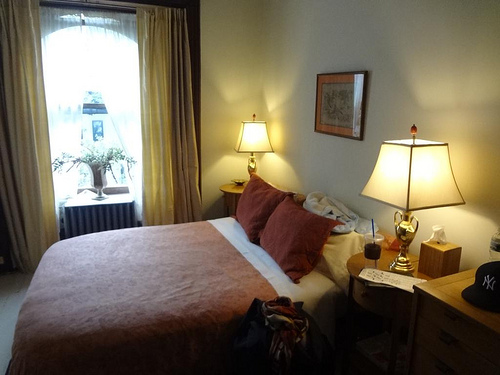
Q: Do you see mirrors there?
A: No, there are no mirrors.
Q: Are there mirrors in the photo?
A: No, there are no mirrors.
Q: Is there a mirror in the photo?
A: No, there are no mirrors.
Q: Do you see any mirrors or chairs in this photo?
A: No, there are no mirrors or chairs.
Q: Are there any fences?
A: No, there are no fences.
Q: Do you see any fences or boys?
A: No, there are no fences or boys.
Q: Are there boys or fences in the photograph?
A: No, there are no fences or boys.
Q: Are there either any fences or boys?
A: No, there are no fences or boys.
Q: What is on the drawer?
A: The cap is on the drawer.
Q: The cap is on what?
A: The cap is on the drawer.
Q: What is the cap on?
A: The cap is on the drawer.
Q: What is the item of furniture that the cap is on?
A: The piece of furniture is a drawer.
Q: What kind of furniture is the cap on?
A: The cap is on the drawer.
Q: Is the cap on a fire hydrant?
A: No, the cap is on a drawer.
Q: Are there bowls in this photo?
A: No, there are no bowls.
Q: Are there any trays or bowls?
A: No, there are no bowls or trays.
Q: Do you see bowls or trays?
A: No, there are no bowls or trays.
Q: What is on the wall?
A: The painting is on the wall.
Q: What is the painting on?
A: The painting is on the wall.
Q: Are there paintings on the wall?
A: Yes, there is a painting on the wall.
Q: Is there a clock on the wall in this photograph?
A: No, there is a painting on the wall.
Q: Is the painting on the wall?
A: Yes, the painting is on the wall.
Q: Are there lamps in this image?
A: Yes, there is a lamp.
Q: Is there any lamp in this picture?
A: Yes, there is a lamp.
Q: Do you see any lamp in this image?
A: Yes, there is a lamp.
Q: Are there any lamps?
A: Yes, there is a lamp.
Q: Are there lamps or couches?
A: Yes, there is a lamp.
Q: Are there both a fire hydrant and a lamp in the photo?
A: No, there is a lamp but no fire hydrants.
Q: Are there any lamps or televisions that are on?
A: Yes, the lamp is on.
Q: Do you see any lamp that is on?
A: Yes, there is a lamp that is on.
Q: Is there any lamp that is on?
A: Yes, there is a lamp that is on.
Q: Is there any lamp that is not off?
A: Yes, there is a lamp that is on.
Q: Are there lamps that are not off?
A: Yes, there is a lamp that is on.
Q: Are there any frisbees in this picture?
A: No, there are no frisbees.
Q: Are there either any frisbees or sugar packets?
A: No, there are no frisbees or sugar packets.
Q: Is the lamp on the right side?
A: Yes, the lamp is on the right of the image.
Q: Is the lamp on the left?
A: No, the lamp is on the right of the image.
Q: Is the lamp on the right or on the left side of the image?
A: The lamp is on the right of the image.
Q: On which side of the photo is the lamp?
A: The lamp is on the right of the image.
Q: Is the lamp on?
A: Yes, the lamp is on.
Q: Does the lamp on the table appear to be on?
A: Yes, the lamp is on.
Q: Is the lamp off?
A: No, the lamp is on.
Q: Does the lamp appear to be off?
A: No, the lamp is on.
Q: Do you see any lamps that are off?
A: No, there is a lamp but it is on.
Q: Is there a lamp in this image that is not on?
A: No, there is a lamp but it is on.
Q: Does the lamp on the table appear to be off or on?
A: The lamp is on.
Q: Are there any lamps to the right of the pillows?
A: Yes, there is a lamp to the right of the pillows.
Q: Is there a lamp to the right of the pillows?
A: Yes, there is a lamp to the right of the pillows.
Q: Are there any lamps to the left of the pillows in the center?
A: No, the lamp is to the right of the pillows.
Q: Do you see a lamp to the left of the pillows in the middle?
A: No, the lamp is to the right of the pillows.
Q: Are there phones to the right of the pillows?
A: No, there is a lamp to the right of the pillows.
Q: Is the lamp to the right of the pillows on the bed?
A: Yes, the lamp is to the right of the pillows.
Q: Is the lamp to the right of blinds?
A: No, the lamp is to the right of the pillows.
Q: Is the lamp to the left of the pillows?
A: No, the lamp is to the right of the pillows.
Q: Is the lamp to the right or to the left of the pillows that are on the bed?
A: The lamp is to the right of the pillows.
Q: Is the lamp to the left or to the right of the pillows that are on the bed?
A: The lamp is to the right of the pillows.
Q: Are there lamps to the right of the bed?
A: Yes, there is a lamp to the right of the bed.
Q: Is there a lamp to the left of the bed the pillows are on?
A: No, the lamp is to the right of the bed.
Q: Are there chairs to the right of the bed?
A: No, there is a lamp to the right of the bed.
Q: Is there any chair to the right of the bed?
A: No, there is a lamp to the right of the bed.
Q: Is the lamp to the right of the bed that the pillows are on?
A: Yes, the lamp is to the right of the bed.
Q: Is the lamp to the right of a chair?
A: No, the lamp is to the right of the bed.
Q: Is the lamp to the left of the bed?
A: No, the lamp is to the right of the bed.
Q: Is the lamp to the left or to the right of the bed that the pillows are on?
A: The lamp is to the right of the bed.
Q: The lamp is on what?
A: The lamp is on the table.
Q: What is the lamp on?
A: The lamp is on the table.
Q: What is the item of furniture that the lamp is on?
A: The piece of furniture is a table.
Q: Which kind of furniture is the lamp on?
A: The lamp is on the table.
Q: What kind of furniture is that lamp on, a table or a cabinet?
A: The lamp is on a table.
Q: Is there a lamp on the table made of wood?
A: Yes, there is a lamp on the table.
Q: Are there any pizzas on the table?
A: No, there is a lamp on the table.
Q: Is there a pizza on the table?
A: No, there is a lamp on the table.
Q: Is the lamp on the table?
A: Yes, the lamp is on the table.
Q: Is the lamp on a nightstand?
A: No, the lamp is on the table.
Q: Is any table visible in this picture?
A: Yes, there is a table.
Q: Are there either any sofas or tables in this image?
A: Yes, there is a table.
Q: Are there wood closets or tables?
A: Yes, there is a wood table.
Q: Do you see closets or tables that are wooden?
A: Yes, the table is wooden.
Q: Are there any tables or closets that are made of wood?
A: Yes, the table is made of wood.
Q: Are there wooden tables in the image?
A: Yes, there is a wood table.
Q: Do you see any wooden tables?
A: Yes, there is a wood table.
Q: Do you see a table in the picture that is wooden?
A: Yes, there is a table that is wooden.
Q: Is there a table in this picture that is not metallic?
A: Yes, there is a wooden table.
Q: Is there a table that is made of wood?
A: Yes, there is a table that is made of wood.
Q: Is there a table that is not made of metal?
A: Yes, there is a table that is made of wood.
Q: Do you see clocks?
A: No, there are no clocks.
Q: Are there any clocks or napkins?
A: No, there are no clocks or napkins.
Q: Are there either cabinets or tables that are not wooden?
A: No, there is a table but it is wooden.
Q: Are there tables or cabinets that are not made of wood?
A: No, there is a table but it is made of wood.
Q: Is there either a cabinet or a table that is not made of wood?
A: No, there is a table but it is made of wood.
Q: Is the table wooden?
A: Yes, the table is wooden.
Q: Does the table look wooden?
A: Yes, the table is wooden.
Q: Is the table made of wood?
A: Yes, the table is made of wood.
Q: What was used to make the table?
A: The table is made of wood.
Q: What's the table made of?
A: The table is made of wood.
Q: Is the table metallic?
A: No, the table is wooden.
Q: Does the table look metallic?
A: No, the table is wooden.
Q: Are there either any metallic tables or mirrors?
A: No, there is a table but it is wooden.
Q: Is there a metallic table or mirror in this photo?
A: No, there is a table but it is wooden.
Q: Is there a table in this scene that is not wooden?
A: No, there is a table but it is wooden.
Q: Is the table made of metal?
A: No, the table is made of wood.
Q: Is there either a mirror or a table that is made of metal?
A: No, there is a table but it is made of wood.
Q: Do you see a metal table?
A: No, there is a table but it is made of wood.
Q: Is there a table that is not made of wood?
A: No, there is a table but it is made of wood.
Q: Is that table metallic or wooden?
A: The table is wooden.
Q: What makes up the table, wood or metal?
A: The table is made of wood.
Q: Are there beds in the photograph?
A: Yes, there is a bed.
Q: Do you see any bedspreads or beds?
A: Yes, there is a bed.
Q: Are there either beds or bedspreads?
A: Yes, there is a bed.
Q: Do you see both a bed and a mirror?
A: No, there is a bed but no mirrors.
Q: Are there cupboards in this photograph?
A: No, there are no cupboards.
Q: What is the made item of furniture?
A: The piece of furniture is a bed.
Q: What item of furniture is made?
A: The piece of furniture is a bed.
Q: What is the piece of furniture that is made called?
A: The piece of furniture is a bed.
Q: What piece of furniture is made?
A: The piece of furniture is a bed.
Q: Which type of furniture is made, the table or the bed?
A: The bed is made.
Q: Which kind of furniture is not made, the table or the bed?
A: The table is not made.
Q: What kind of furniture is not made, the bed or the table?
A: The table is not made.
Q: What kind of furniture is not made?
A: The furniture is a table.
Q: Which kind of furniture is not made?
A: The furniture is a table.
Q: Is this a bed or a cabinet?
A: This is a bed.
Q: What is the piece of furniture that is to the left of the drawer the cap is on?
A: The piece of furniture is a bed.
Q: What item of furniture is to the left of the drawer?
A: The piece of furniture is a bed.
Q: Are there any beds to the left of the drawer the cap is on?
A: Yes, there is a bed to the left of the drawer.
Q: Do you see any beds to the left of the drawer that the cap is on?
A: Yes, there is a bed to the left of the drawer.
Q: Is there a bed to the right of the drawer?
A: No, the bed is to the left of the drawer.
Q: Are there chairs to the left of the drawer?
A: No, there is a bed to the left of the drawer.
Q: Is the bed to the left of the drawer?
A: Yes, the bed is to the left of the drawer.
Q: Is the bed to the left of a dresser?
A: No, the bed is to the left of the drawer.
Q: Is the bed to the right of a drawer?
A: No, the bed is to the left of a drawer.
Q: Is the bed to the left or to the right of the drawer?
A: The bed is to the left of the drawer.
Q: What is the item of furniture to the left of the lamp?
A: The piece of furniture is a bed.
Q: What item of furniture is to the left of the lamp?
A: The piece of furniture is a bed.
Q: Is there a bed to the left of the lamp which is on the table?
A: Yes, there is a bed to the left of the lamp.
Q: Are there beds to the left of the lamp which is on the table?
A: Yes, there is a bed to the left of the lamp.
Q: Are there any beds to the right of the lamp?
A: No, the bed is to the left of the lamp.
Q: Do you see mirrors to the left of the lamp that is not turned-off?
A: No, there is a bed to the left of the lamp.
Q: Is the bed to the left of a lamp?
A: Yes, the bed is to the left of a lamp.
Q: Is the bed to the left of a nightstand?
A: No, the bed is to the left of a lamp.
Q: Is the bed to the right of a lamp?
A: No, the bed is to the left of a lamp.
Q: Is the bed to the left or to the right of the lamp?
A: The bed is to the left of the lamp.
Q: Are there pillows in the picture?
A: Yes, there are pillows.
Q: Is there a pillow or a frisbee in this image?
A: Yes, there are pillows.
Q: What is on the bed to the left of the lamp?
A: The pillows are on the bed.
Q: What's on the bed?
A: The pillows are on the bed.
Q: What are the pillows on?
A: The pillows are on the bed.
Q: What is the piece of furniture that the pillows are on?
A: The piece of furniture is a bed.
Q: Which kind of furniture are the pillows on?
A: The pillows are on the bed.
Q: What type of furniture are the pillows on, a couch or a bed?
A: The pillows are on a bed.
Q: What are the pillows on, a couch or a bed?
A: The pillows are on a bed.